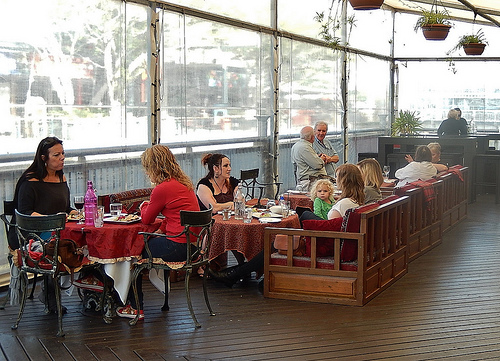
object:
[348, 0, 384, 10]
planter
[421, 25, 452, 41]
planter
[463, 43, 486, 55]
planter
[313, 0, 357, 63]
plant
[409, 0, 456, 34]
plant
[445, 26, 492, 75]
plant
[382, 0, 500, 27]
ceiling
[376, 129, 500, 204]
dark counter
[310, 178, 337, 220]
child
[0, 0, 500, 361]
restaurant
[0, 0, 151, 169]
window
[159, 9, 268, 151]
window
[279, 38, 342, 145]
window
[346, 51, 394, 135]
window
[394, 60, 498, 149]
window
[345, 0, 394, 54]
window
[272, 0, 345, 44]
window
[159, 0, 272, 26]
window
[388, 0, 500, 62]
window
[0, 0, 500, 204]
wall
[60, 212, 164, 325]
table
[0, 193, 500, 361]
wood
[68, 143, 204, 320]
lady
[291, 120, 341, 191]
men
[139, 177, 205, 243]
shirt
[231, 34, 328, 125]
plants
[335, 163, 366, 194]
head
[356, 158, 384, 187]
head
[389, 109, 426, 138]
plant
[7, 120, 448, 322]
people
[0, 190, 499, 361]
floor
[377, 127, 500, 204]
table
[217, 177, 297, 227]
diner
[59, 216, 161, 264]
red tablecloth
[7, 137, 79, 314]
lady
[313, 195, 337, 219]
green shirt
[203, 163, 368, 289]
woman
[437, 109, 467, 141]
person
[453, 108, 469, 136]
person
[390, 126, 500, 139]
ledge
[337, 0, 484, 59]
pots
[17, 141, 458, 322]
setting